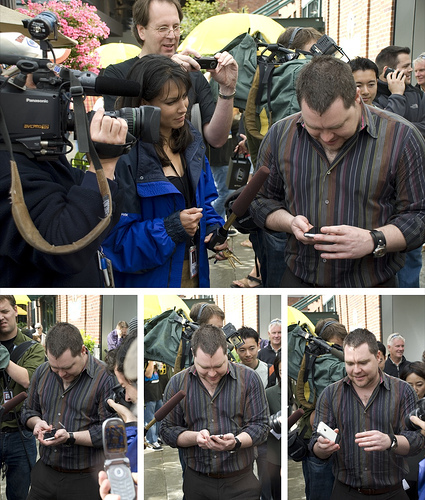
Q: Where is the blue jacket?
A: On woman.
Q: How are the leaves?
A: Light green.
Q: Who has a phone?
A: The man.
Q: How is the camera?
A: Black.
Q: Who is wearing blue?
A: The lady.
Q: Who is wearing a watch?
A: The man.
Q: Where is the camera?
A: Hand.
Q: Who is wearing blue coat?
A: Lady.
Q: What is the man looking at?
A: Phone.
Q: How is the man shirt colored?
A: Green red black.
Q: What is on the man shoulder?
A: Camera.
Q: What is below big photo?
A: 3 photos.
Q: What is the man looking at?
A: His phone.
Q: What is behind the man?
A: Crowd.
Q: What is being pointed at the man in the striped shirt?
A: Camera.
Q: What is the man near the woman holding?
A: Phone.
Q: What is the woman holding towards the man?
A: Microphone.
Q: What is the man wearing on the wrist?
A: Watch.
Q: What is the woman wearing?
A: Jacket.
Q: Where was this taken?
A: Outside at a news conference.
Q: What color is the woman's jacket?
A: Blue.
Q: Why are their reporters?
A: Doing a interview.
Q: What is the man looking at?
A: A phone.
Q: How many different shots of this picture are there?
A: Four.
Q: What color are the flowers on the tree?
A: Pink.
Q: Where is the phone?
A: In the man's hand.